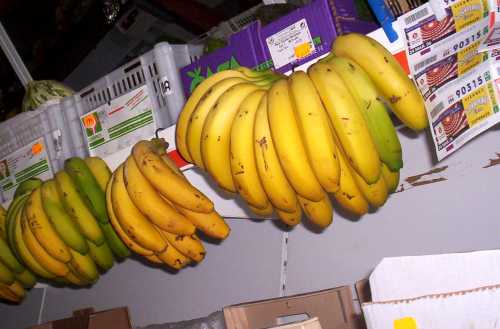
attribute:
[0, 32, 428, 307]
bananas — hanging, yellow, bunched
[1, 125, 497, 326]
wall — white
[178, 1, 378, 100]
cardboard — purple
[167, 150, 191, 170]
stripe — orange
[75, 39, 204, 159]
bin — plastic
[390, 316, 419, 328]
sticker — yellow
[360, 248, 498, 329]
box — white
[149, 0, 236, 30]
ceiling — brown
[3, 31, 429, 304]
bunch — large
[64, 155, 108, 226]
banana — green, bruised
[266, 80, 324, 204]
banana — yellow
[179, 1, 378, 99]
box — purple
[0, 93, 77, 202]
crate — white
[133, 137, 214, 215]
banana — bruised